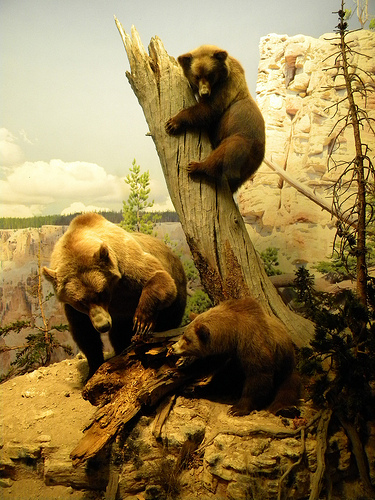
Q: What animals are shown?
A: Bears.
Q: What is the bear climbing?
A: Tree.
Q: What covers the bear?
A: Fur.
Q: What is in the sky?
A: Clouds.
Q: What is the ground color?
A: Brown.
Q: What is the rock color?
A: White.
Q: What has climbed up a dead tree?
A: A small bear.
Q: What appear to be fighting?
A: Two brown bears.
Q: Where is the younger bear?
A: In a dead tree.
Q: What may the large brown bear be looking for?
A: Food.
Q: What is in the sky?
A: Clouds.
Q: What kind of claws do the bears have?
A: Long and sharp.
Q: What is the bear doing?
A: Climbing.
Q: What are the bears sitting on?
A: A rock.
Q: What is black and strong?
A: The bear.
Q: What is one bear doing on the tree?
A: Climbing.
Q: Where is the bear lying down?
A: To the right.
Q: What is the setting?
A: A wildlife habitat.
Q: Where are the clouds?
A: In the sky.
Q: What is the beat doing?
A: Hanging onto a tree.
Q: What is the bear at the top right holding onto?
A: Tree.